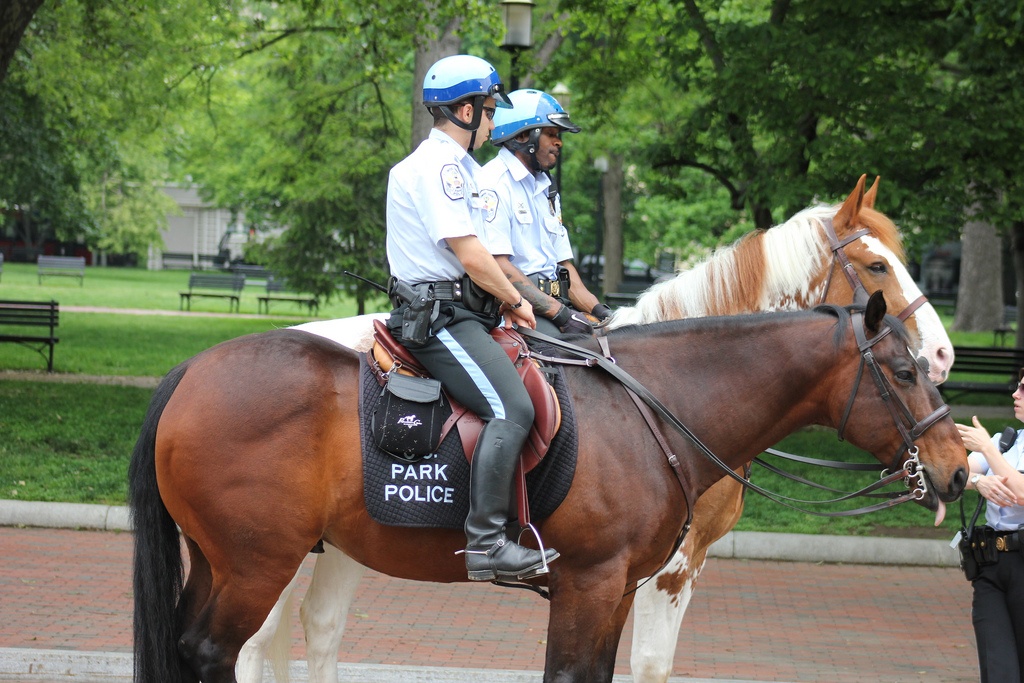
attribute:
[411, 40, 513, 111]
helmet — blue, white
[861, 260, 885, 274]
eye — horse's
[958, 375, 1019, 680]
woman — black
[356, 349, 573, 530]
saddle — black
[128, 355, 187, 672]
tail — black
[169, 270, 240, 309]
bench — park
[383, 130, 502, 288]
uniform shirt — police